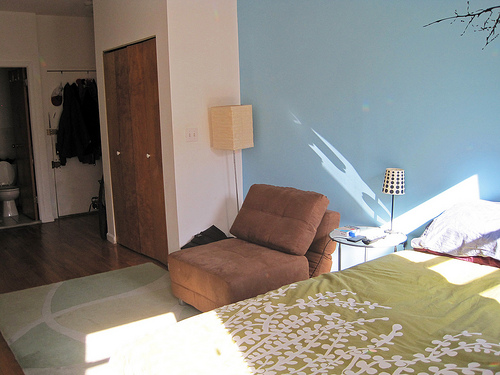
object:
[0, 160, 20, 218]
toilet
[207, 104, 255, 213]
lamp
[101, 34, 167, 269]
door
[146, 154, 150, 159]
knob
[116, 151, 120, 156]
knob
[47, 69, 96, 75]
bar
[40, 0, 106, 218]
closet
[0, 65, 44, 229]
bathroom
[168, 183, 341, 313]
chair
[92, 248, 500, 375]
bedspread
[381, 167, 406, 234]
lamp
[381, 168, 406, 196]
shade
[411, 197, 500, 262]
pillow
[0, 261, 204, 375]
rug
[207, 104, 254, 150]
shade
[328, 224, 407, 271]
table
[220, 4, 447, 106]
wall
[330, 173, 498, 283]
sunlight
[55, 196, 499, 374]
bed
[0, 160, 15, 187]
lid